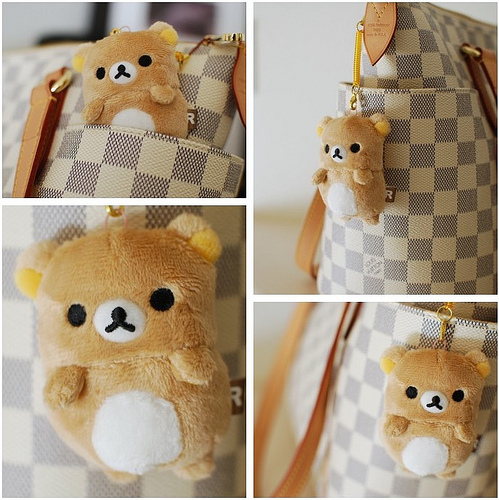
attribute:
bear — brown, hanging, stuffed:
[69, 17, 192, 141]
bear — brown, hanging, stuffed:
[306, 108, 397, 229]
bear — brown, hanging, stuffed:
[11, 207, 237, 491]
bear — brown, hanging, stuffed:
[374, 341, 495, 486]